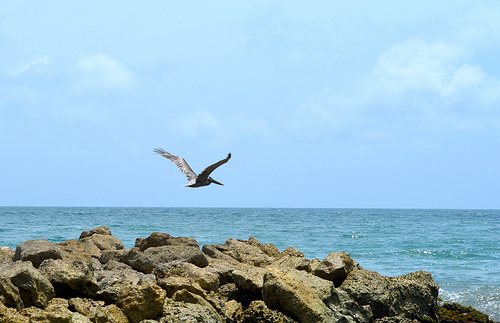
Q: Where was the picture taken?
A: It was taken at the ocean.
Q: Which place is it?
A: It is an ocean.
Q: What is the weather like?
A: It is cloudy.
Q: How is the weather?
A: It is cloudy.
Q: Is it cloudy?
A: Yes, it is cloudy.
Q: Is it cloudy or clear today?
A: It is cloudy.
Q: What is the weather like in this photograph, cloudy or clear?
A: It is cloudy.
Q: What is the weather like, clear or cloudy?
A: It is cloudy.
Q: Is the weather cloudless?
A: No, it is cloudy.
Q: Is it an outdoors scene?
A: Yes, it is outdoors.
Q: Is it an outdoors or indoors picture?
A: It is outdoors.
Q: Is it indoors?
A: No, it is outdoors.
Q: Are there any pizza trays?
A: No, there are no pizza trays.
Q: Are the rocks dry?
A: Yes, the rocks are dry.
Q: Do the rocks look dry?
A: Yes, the rocks are dry.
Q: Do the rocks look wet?
A: No, the rocks are dry.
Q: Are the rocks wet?
A: No, the rocks are dry.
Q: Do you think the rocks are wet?
A: No, the rocks are dry.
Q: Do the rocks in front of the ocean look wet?
A: No, the rocks are dry.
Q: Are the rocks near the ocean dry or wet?
A: The rocks are dry.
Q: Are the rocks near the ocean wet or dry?
A: The rocks are dry.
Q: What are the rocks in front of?
A: The rocks are in front of the ocean.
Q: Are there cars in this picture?
A: No, there are no cars.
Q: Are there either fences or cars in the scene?
A: No, there are no cars or fences.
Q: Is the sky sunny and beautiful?
A: No, the sky is beautiful but cloudy.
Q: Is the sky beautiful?
A: Yes, the sky is beautiful.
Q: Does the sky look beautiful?
A: Yes, the sky is beautiful.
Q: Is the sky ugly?
A: No, the sky is beautiful.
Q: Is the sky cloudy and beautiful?
A: Yes, the sky is cloudy and beautiful.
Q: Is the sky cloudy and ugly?
A: No, the sky is cloudy but beautiful.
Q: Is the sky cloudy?
A: Yes, the sky is cloudy.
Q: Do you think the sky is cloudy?
A: Yes, the sky is cloudy.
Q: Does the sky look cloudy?
A: Yes, the sky is cloudy.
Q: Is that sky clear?
A: No, the sky is cloudy.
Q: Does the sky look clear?
A: No, the sky is cloudy.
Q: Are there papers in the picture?
A: No, there are no papers.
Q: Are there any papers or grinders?
A: No, there are no papers or grinders.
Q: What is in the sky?
A: The clouds are in the sky.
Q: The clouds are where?
A: The clouds are in the sky.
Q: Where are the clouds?
A: The clouds are in the sky.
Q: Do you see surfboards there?
A: No, there are no surfboards.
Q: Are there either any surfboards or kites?
A: No, there are no surfboards or kites.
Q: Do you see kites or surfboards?
A: No, there are no surfboards or kites.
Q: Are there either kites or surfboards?
A: No, there are no surfboards or kites.